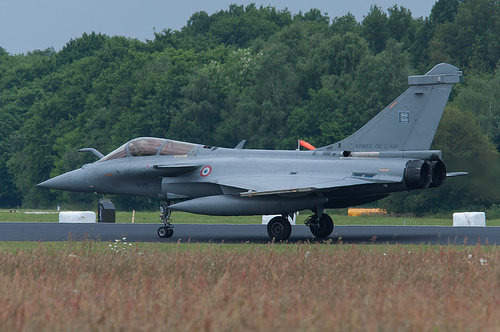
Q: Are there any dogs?
A: No, there are no dogs.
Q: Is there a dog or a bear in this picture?
A: No, there are no dogs or bears.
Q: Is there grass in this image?
A: Yes, there is grass.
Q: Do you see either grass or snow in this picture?
A: Yes, there is grass.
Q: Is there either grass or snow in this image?
A: Yes, there is grass.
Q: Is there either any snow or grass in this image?
A: Yes, there is grass.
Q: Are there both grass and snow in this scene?
A: No, there is grass but no snow.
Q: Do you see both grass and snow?
A: No, there is grass but no snow.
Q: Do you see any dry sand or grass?
A: Yes, there is dry grass.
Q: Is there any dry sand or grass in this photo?
A: Yes, there is dry grass.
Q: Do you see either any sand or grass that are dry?
A: Yes, the grass is dry.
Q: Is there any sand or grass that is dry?
A: Yes, the grass is dry.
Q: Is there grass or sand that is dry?
A: Yes, the grass is dry.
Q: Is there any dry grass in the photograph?
A: Yes, there is dry grass.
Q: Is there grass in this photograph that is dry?
A: Yes, there is dry grass.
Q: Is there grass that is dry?
A: Yes, there is grass that is dry.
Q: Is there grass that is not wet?
A: Yes, there is dry grass.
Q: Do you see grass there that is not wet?
A: Yes, there is dry grass.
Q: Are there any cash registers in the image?
A: No, there are no cash registers.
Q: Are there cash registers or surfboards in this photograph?
A: No, there are no cash registers or surfboards.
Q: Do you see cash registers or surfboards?
A: No, there are no cash registers or surfboards.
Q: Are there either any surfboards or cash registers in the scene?
A: No, there are no cash registers or surfboards.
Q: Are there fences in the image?
A: No, there are no fences.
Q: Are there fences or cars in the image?
A: No, there are no fences or cars.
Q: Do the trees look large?
A: Yes, the trees are large.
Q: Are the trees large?
A: Yes, the trees are large.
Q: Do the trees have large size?
A: Yes, the trees are large.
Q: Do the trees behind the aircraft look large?
A: Yes, the trees are large.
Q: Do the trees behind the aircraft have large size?
A: Yes, the trees are large.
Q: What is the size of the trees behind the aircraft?
A: The trees are large.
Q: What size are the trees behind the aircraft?
A: The trees are large.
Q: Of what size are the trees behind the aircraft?
A: The trees are large.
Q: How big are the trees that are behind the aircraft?
A: The trees are large.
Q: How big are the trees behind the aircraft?
A: The trees are large.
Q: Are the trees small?
A: No, the trees are large.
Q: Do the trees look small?
A: No, the trees are large.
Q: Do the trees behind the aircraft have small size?
A: No, the trees are large.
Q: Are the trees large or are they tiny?
A: The trees are large.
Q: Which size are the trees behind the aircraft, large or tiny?
A: The trees are large.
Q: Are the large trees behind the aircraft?
A: Yes, the trees are behind the aircraft.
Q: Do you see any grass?
A: Yes, there is grass.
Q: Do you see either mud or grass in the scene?
A: Yes, there is grass.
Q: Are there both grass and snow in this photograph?
A: No, there is grass but no snow.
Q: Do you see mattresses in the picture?
A: No, there are no mattresses.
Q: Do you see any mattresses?
A: No, there are no mattresses.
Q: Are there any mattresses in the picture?
A: No, there are no mattresses.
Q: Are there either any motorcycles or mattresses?
A: No, there are no mattresses or motorcycles.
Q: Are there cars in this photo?
A: No, there are no cars.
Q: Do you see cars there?
A: No, there are no cars.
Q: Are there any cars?
A: No, there are no cars.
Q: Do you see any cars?
A: No, there are no cars.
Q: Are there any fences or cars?
A: No, there are no cars or fences.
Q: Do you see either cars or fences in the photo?
A: No, there are no cars or fences.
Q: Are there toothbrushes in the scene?
A: No, there are no toothbrushes.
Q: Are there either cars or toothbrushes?
A: No, there are no toothbrushes or cars.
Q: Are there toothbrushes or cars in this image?
A: No, there are no toothbrushes or cars.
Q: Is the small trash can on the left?
A: Yes, the trashcan is on the left of the image.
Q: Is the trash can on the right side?
A: No, the trash can is on the left of the image.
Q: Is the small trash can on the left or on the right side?
A: The garbage bin is on the left of the image.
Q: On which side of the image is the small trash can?
A: The trash bin is on the left of the image.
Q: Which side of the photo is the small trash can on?
A: The trash bin is on the left of the image.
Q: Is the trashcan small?
A: Yes, the trashcan is small.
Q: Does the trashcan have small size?
A: Yes, the trashcan is small.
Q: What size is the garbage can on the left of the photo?
A: The garbage can is small.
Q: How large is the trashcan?
A: The trashcan is small.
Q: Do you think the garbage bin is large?
A: No, the garbage bin is small.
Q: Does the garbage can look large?
A: No, the garbage can is small.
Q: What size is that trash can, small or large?
A: The trash can is small.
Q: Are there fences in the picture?
A: No, there are no fences.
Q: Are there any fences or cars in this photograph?
A: No, there are no fences or cars.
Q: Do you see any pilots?
A: No, there are no pilots.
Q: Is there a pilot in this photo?
A: No, there are no pilots.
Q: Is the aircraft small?
A: Yes, the aircraft is small.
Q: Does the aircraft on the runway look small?
A: Yes, the aircraft is small.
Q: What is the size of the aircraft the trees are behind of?
A: The aircraft is small.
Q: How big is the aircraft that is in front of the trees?
A: The aircraft is small.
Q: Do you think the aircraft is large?
A: No, the aircraft is small.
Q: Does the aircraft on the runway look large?
A: No, the aircraft is small.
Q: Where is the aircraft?
A: The aircraft is on the runway.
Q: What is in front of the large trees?
A: The aircraft is in front of the trees.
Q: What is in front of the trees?
A: The aircraft is in front of the trees.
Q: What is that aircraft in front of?
A: The aircraft is in front of the trees.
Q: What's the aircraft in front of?
A: The aircraft is in front of the trees.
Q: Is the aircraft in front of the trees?
A: Yes, the aircraft is in front of the trees.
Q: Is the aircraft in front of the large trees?
A: Yes, the aircraft is in front of the trees.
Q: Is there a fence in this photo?
A: No, there are no fences.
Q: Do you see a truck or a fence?
A: No, there are no fences or trucks.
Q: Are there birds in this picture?
A: No, there are no birds.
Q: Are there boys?
A: No, there are no boys.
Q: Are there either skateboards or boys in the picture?
A: No, there are no boys or skateboards.